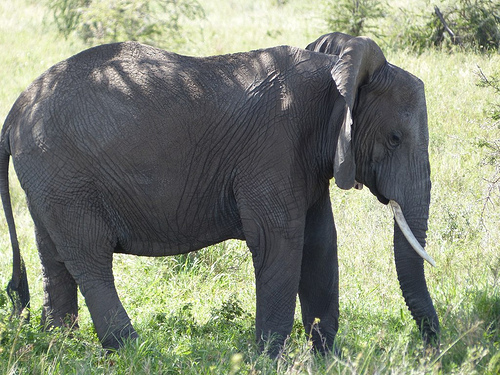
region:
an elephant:
[2, 30, 441, 362]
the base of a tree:
[426, 2, 498, 49]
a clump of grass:
[2, 288, 124, 373]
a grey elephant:
[2, 30, 445, 362]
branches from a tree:
[473, 60, 498, 240]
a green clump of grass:
[467, 280, 496, 339]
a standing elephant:
[2, 31, 444, 363]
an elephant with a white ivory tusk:
[2, 30, 442, 365]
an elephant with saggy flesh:
[0, 31, 452, 369]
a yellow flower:
[307, 315, 332, 355]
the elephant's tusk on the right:
[387, 200, 433, 267]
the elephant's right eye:
[385, 130, 395, 145]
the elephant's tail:
[0, 130, 30, 321]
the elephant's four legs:
[33, 201, 339, 355]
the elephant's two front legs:
[240, 208, 337, 359]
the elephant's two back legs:
[30, 238, 140, 351]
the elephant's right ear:
[330, 36, 376, 191]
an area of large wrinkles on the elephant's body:
[177, 91, 254, 238]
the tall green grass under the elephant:
[3, 245, 450, 373]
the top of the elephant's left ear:
[308, 32, 354, 52]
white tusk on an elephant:
[382, 197, 442, 271]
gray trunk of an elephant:
[382, 187, 446, 351]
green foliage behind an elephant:
[307, 0, 491, 55]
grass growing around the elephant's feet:
[2, 289, 450, 367]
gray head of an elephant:
[320, 3, 463, 365]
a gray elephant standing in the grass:
[0, 39, 457, 364]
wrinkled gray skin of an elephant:
[184, 66, 289, 231]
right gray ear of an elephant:
[327, 34, 387, 192]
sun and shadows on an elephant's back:
[52, 37, 302, 117]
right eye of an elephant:
[384, 129, 403, 150]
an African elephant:
[1, 0, 498, 372]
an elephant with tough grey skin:
[0, 32, 455, 374]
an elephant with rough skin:
[10, 17, 463, 372]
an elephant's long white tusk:
[381, 193, 446, 267]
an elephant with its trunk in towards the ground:
[23, 29, 498, 357]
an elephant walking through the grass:
[0, 23, 488, 372]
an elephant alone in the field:
[0, 2, 495, 367]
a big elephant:
[0, 0, 495, 366]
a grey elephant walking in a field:
[0, 8, 496, 368]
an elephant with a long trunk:
[5, 26, 467, 358]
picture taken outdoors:
[11, 160, 487, 367]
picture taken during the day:
[22, 26, 457, 371]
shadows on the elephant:
[54, 38, 444, 209]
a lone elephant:
[21, 46, 351, 373]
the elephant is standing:
[39, 71, 485, 323]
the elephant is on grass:
[57, 273, 379, 354]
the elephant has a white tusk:
[391, 187, 457, 292]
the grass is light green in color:
[135, 228, 417, 340]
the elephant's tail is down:
[3, 122, 22, 340]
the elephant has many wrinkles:
[57, 88, 345, 225]